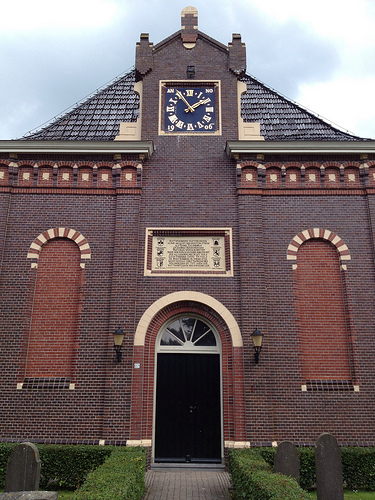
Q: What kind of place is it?
A: It is a church.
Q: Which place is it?
A: It is a church.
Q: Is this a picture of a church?
A: Yes, it is showing a church.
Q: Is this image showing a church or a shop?
A: It is showing a church.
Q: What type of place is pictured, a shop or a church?
A: It is a church.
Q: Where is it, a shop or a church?
A: It is a church.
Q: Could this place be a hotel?
A: No, it is a church.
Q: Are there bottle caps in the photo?
A: No, there are no bottle caps.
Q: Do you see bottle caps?
A: No, there are no bottle caps.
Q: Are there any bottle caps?
A: No, there are no bottle caps.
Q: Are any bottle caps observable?
A: No, there are no bottle caps.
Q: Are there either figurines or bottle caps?
A: No, there are no bottle caps or figurines.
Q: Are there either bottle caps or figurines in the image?
A: No, there are no bottle caps or figurines.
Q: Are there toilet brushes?
A: No, there are no toilet brushes.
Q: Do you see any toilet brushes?
A: No, there are no toilet brushes.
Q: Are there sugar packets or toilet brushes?
A: No, there are no toilet brushes or sugar packets.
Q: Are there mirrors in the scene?
A: No, there are no mirrors.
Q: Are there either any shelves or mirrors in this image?
A: No, there are no mirrors or shelves.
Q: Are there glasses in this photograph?
A: No, there are no glasses.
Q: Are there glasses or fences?
A: No, there are no glasses or fences.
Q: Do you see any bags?
A: No, there are no bags.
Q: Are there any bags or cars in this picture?
A: No, there are no bags or cars.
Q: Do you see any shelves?
A: No, there are no shelves.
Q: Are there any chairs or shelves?
A: No, there are no shelves or chairs.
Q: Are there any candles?
A: No, there are no candles.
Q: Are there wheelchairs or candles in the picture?
A: No, there are no candles or wheelchairs.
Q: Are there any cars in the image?
A: No, there are no cars.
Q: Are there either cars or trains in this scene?
A: No, there are no cars or trains.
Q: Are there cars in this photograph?
A: No, there are no cars.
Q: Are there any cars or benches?
A: No, there are no cars or benches.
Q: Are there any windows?
A: Yes, there is a window.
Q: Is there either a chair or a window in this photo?
A: Yes, there is a window.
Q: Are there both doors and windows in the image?
A: Yes, there are both a window and a door.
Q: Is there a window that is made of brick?
A: Yes, there is a window that is made of brick.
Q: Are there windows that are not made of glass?
A: Yes, there is a window that is made of brick.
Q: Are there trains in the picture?
A: No, there are no trains.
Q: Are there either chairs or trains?
A: No, there are no trains or chairs.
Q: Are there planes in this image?
A: No, there are no planes.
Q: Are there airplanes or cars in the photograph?
A: No, there are no airplanes or cars.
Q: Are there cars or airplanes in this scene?
A: No, there are no airplanes or cars.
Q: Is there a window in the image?
A: Yes, there is a window.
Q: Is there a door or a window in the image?
A: Yes, there is a window.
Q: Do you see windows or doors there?
A: Yes, there is a window.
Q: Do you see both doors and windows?
A: Yes, there are both a window and a door.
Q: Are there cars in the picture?
A: No, there are no cars.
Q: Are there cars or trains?
A: No, there are no cars or trains.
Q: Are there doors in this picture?
A: Yes, there is a door.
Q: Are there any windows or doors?
A: Yes, there is a door.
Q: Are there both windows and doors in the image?
A: Yes, there are both a door and a window.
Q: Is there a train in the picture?
A: No, there are no trains.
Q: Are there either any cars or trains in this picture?
A: No, there are no trains or cars.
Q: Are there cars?
A: No, there are no cars.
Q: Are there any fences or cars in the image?
A: No, there are no cars or fences.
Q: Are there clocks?
A: Yes, there is a clock.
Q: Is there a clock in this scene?
A: Yes, there is a clock.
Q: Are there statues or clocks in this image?
A: Yes, there is a clock.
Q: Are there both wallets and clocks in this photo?
A: No, there is a clock but no wallets.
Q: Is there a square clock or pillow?
A: Yes, there is a square clock.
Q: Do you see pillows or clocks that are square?
A: Yes, the clock is square.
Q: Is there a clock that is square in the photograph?
A: Yes, there is a square clock.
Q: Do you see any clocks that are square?
A: Yes, there is a clock that is square.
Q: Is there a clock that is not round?
A: Yes, there is a square clock.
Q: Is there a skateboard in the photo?
A: No, there are no skateboards.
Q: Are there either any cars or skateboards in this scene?
A: No, there are no skateboards or cars.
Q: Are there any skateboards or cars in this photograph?
A: No, there are no skateboards or cars.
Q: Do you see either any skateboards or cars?
A: No, there are no skateboards or cars.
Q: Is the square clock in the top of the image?
A: Yes, the clock is in the top of the image.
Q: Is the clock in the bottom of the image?
A: No, the clock is in the top of the image.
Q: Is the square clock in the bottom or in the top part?
A: The clock is in the top of the image.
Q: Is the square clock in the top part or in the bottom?
A: The clock is in the top of the image.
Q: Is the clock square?
A: Yes, the clock is square.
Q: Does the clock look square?
A: Yes, the clock is square.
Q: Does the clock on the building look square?
A: Yes, the clock is square.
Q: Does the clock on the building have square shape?
A: Yes, the clock is square.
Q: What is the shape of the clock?
A: The clock is square.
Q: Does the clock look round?
A: No, the clock is square.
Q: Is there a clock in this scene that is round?
A: No, there is a clock but it is square.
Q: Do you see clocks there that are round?
A: No, there is a clock but it is square.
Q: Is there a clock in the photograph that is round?
A: No, there is a clock but it is square.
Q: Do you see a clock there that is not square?
A: No, there is a clock but it is square.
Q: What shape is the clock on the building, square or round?
A: The clock is square.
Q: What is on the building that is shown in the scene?
A: The clock is on the building.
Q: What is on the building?
A: The clock is on the building.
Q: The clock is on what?
A: The clock is on the building.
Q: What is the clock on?
A: The clock is on the building.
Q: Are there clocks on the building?
A: Yes, there is a clock on the building.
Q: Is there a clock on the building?
A: Yes, there is a clock on the building.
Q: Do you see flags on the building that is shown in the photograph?
A: No, there is a clock on the building.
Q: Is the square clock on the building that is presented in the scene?
A: Yes, the clock is on the building.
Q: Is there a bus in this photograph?
A: No, there are no buses.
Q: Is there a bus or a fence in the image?
A: No, there are no buses or fences.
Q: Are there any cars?
A: No, there are no cars.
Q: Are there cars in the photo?
A: No, there are no cars.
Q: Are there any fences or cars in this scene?
A: No, there are no cars or fences.